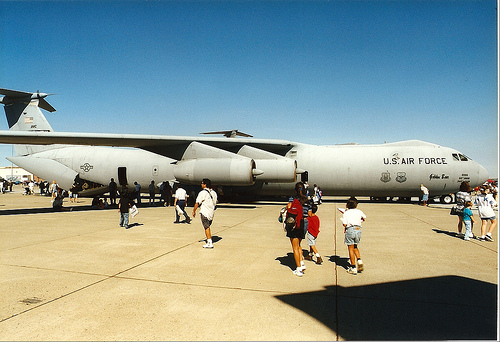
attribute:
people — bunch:
[1, 170, 498, 273]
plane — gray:
[7, 92, 498, 194]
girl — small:
[461, 200, 473, 242]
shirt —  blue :
[462, 207, 471, 221]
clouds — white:
[200, 28, 396, 104]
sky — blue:
[2, 3, 494, 188]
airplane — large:
[3, 84, 491, 209]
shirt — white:
[195, 188, 220, 219]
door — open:
[117, 165, 127, 185]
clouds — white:
[210, 53, 290, 120]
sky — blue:
[316, 21, 375, 70]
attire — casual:
[191, 186, 221, 232]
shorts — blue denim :
[305, 231, 319, 247]